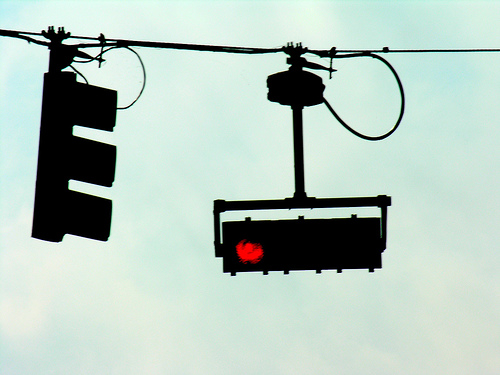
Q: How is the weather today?
A: It is clear.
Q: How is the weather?
A: It is clear.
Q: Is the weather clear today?
A: Yes, it is clear.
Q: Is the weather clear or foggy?
A: It is clear.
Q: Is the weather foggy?
A: No, it is clear.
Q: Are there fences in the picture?
A: No, there are no fences.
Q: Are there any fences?
A: No, there are no fences.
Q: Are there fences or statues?
A: No, there are no fences or statues.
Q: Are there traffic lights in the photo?
A: Yes, there is a traffic light.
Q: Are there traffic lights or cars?
A: Yes, there is a traffic light.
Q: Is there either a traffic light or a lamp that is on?
A: Yes, the traffic light is on.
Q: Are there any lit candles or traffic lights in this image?
A: Yes, there is a lit traffic light.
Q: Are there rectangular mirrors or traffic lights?
A: Yes, there is a rectangular traffic light.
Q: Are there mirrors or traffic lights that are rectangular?
A: Yes, the traffic light is rectangular.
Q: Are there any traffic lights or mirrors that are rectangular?
A: Yes, the traffic light is rectangular.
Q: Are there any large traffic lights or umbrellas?
A: Yes, there is a large traffic light.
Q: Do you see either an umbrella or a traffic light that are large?
A: Yes, the traffic light is large.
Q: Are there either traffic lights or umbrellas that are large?
A: Yes, the traffic light is large.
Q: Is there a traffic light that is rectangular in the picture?
A: Yes, there is a rectangular traffic light.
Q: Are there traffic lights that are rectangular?
A: Yes, there is a traffic light that is rectangular.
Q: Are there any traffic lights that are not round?
A: Yes, there is a rectangular traffic light.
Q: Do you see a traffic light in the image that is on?
A: Yes, there is a traffic light that is on.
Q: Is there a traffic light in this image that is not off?
A: Yes, there is a traffic light that is on.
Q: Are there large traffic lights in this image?
A: Yes, there is a large traffic light.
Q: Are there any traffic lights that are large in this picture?
A: Yes, there is a large traffic light.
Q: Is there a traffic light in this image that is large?
A: Yes, there is a traffic light that is large.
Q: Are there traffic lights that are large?
A: Yes, there is a traffic light that is large.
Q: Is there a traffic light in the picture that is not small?
A: Yes, there is a large traffic light.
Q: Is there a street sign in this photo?
A: No, there are no street signs.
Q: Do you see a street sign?
A: No, there are no street signs.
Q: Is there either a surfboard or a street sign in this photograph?
A: No, there are no street signs or surfboards.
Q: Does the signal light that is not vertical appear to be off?
A: No, the traffic signal is on.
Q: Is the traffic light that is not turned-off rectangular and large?
A: Yes, the traffic light is rectangular and large.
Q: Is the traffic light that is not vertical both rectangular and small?
A: No, the traffic signal is rectangular but large.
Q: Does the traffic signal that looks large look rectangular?
A: Yes, the signal light is rectangular.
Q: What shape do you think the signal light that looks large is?
A: The signal light is rectangular.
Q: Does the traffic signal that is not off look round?
A: No, the signal light is rectangular.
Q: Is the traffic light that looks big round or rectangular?
A: The traffic light is rectangular.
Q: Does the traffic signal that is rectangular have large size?
A: Yes, the signal light is large.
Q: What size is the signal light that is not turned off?
A: The signal light is large.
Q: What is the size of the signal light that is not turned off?
A: The signal light is large.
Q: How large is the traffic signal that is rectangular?
A: The traffic light is large.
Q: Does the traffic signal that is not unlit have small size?
A: No, the traffic light is large.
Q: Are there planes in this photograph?
A: No, there are no planes.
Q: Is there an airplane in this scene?
A: No, there are no airplanes.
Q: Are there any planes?
A: No, there are no planes.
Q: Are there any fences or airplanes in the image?
A: No, there are no airplanes or fences.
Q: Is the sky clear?
A: Yes, the sky is clear.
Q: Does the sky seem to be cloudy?
A: No, the sky is clear.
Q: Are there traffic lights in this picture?
A: Yes, there is a traffic light.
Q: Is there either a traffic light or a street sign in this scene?
A: Yes, there is a traffic light.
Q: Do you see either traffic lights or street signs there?
A: Yes, there is a traffic light.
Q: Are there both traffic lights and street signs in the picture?
A: No, there is a traffic light but no street signs.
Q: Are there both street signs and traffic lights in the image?
A: No, there is a traffic light but no street signs.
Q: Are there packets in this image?
A: No, there are no packets.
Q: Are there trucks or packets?
A: No, there are no packets or trucks.